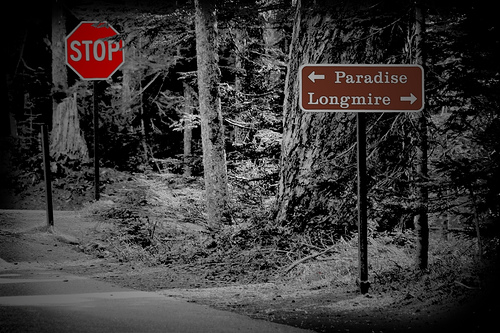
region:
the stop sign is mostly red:
[51, 8, 127, 85]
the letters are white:
[67, 30, 119, 65]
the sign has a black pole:
[57, 13, 146, 217]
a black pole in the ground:
[28, 103, 68, 239]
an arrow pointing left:
[293, 62, 337, 88]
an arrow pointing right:
[398, 85, 433, 110]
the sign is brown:
[273, 32, 430, 129]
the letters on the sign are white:
[308, 70, 407, 107]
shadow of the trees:
[10, 246, 137, 313]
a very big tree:
[261, 0, 468, 259]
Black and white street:
[75, 305, 96, 320]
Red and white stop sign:
[68, 29, 134, 78]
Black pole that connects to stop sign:
[91, 110, 105, 148]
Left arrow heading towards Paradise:
[301, 63, 421, 87]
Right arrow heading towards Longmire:
[303, 88, 421, 108]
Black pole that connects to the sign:
[354, 154, 377, 251]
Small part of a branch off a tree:
[243, 85, 263, 105]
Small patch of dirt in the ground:
[373, 296, 398, 314]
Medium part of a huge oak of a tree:
[278, 152, 350, 225]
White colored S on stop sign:
[68, 40, 83, 62]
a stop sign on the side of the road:
[51, 12, 201, 255]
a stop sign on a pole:
[47, 21, 169, 256]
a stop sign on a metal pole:
[49, 6, 224, 236]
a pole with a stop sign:
[44, 2, 201, 225]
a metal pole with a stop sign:
[58, 14, 178, 218]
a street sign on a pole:
[254, 29, 470, 331]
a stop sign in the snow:
[53, 14, 189, 238]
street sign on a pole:
[257, 37, 492, 324]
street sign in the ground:
[257, 24, 490, 329]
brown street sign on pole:
[232, 34, 475, 305]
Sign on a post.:
[56, 14, 148, 212]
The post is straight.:
[83, 69, 111, 217]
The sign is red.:
[55, 15, 142, 89]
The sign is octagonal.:
[56, 15, 144, 95]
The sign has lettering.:
[60, 13, 135, 87]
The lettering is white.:
[60, 14, 135, 86]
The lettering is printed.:
[57, 17, 134, 89]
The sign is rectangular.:
[286, 57, 431, 126]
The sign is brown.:
[288, 44, 432, 134]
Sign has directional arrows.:
[290, 56, 430, 126]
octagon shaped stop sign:
[52, 15, 130, 85]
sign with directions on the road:
[292, 60, 428, 117]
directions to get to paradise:
[304, 67, 416, 86]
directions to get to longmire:
[303, 89, 420, 108]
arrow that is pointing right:
[395, 90, 418, 106]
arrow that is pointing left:
[306, 71, 328, 83]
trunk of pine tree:
[188, 18, 237, 228]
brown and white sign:
[290, 63, 429, 115]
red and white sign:
[57, 15, 127, 85]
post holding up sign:
[354, 116, 373, 296]